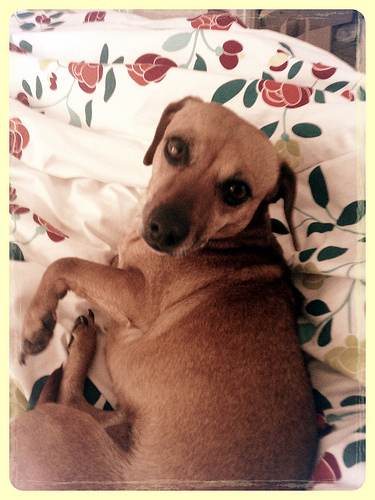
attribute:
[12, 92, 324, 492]
dog — small, one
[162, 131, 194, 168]
eye — brown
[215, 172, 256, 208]
eye — brown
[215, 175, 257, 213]
eye — brown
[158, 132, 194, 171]
eye — brown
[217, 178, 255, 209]
eye — brown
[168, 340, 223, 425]
fur — brown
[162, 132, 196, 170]
eye — big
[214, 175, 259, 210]
eye — big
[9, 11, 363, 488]
bed cover — white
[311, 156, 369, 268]
leaves — some 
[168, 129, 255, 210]
eyes — canine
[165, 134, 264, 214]
eyes — canine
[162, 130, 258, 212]
eyes — canine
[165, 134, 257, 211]
eyes — canine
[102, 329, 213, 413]
stomach — canine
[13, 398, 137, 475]
hip — canine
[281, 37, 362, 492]
sheet — one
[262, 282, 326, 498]
back — one, canine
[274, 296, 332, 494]
back — one, canine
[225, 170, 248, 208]
eye — canine, brown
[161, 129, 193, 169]
eye — brown, canine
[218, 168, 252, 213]
ring — black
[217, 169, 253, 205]
eye — one, canine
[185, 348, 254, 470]
fur — canine, brown, back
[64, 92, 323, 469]
dog — one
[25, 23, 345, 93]
blanket — one, printed, floral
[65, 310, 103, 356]
claws — black, canine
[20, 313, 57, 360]
pads — black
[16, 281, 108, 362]
feet — canine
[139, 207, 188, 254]
nose — canine, black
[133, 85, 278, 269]
head — canine, lifted